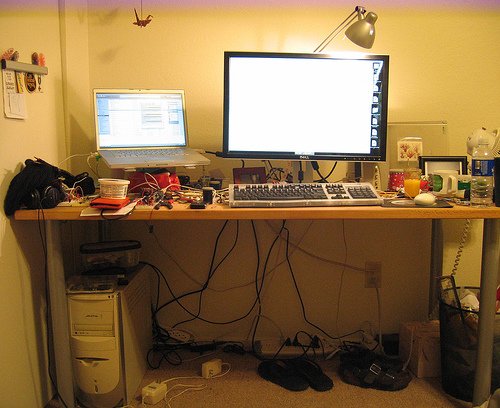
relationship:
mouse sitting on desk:
[412, 191, 436, 207] [0, 191, 496, 246]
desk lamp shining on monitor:
[311, 5, 378, 52] [222, 48, 386, 161]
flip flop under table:
[258, 360, 309, 391] [12, 158, 494, 229]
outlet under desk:
[345, 254, 392, 294] [13, 167, 498, 403]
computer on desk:
[203, 54, 410, 224] [13, 167, 498, 403]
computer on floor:
[66, 263, 155, 407] [149, 344, 494, 405]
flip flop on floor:
[288, 356, 333, 391] [175, 342, 300, 393]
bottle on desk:
[479, 99, 485, 203] [72, 180, 482, 282]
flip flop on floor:
[257, 356, 309, 393] [139, 343, 455, 406]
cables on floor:
[133, 357, 234, 404] [139, 343, 455, 406]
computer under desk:
[64, 260, 159, 405] [37, 137, 485, 257]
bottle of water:
[454, 111, 484, 179] [463, 135, 498, 210]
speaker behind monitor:
[349, 158, 381, 195] [222, 48, 386, 161]